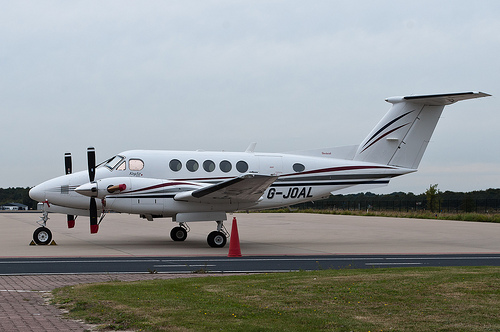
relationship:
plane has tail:
[22, 84, 497, 253] [317, 84, 494, 204]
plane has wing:
[22, 84, 497, 253] [173, 167, 281, 213]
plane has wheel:
[22, 84, 497, 253] [27, 226, 60, 250]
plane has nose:
[22, 84, 497, 253] [26, 163, 99, 217]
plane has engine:
[22, 84, 497, 253] [70, 175, 221, 214]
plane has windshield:
[22, 84, 497, 253] [101, 152, 128, 173]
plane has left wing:
[22, 84, 497, 253] [166, 170, 285, 210]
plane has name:
[22, 84, 497, 253] [263, 184, 318, 203]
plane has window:
[22, 84, 497, 253] [165, 155, 186, 176]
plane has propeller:
[22, 84, 497, 253] [86, 193, 108, 237]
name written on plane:
[263, 184, 318, 203] [22, 84, 497, 253]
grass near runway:
[46, 262, 499, 332] [0, 204, 499, 280]